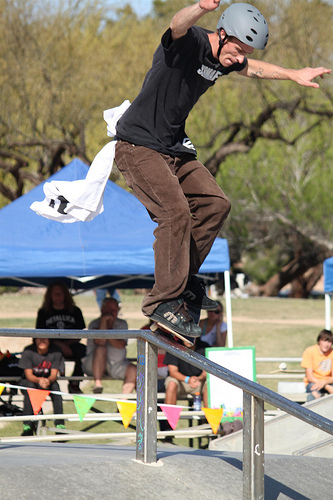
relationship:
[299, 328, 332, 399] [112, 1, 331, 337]
boy watching skateboarder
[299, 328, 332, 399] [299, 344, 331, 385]
boy wearing shirt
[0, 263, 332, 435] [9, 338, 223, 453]
people sitting on bleachers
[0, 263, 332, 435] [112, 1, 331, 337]
people watching skateboarder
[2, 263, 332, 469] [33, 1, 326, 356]
people watching skateboarder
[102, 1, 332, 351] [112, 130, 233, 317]
boy wearing brown pants